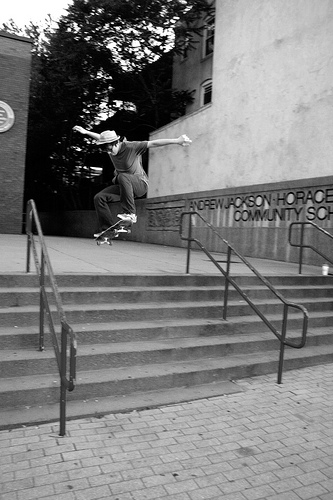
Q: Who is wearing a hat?
A: The boy.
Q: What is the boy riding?
A: A skateboard.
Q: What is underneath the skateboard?
A: Wheels.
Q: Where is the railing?
A: Attached to the steps.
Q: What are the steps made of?
A: Concrete.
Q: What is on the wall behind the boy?
A: A school name.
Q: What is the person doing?
A: Skating.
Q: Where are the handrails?
A: On the stairs.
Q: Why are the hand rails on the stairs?
A: Safety.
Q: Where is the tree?
A: Beside the buildings.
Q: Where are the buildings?
A: Beside the walkway.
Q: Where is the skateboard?
A: In the air.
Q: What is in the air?
A: The skater.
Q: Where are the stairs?
A: Under the skater.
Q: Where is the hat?
A: On the man's head.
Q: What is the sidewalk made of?
A: Bricks.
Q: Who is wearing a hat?
A: The skateboarder.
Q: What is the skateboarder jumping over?
A: The stairs.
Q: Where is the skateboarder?
A: Andrew Jackson Horace Community School.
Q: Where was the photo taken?
A: At a school.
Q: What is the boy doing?
A: Skateboarding.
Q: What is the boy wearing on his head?
A: A hat.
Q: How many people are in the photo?
A: One.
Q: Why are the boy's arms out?
A: He is doing a trick.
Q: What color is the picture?
A: Black and white.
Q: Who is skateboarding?
A: A boy.